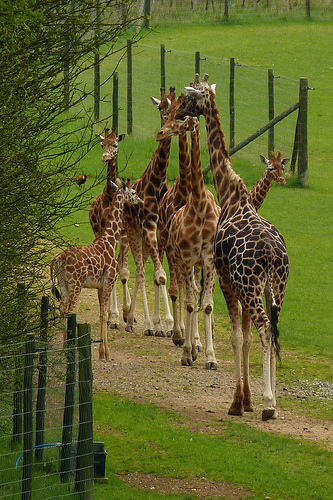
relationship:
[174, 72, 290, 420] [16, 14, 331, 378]
giraffe standing in grass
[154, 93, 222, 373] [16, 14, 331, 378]
giraffe standing in grass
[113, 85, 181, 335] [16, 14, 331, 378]
giraffe standing in grass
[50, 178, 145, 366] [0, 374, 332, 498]
giraffe standing in grass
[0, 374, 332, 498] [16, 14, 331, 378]
grass standing in grass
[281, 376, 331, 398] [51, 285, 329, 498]
rocks on ground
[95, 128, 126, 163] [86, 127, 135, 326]
head of giraffe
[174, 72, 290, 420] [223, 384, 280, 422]
giraffe has hooves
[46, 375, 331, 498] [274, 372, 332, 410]
grass next to rocks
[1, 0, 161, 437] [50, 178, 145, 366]
tree by giraffe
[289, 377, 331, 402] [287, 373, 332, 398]
pile of rocks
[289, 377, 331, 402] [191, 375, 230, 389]
pile of rocks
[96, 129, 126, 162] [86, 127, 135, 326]
head of a giraffe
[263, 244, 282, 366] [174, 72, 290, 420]
tail of a giraffe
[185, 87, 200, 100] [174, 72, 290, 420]
ear of a giraffe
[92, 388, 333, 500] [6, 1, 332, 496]
grass on ground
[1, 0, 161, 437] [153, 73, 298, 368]
tree near giraffes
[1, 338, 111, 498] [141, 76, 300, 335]
fence next to giraffes